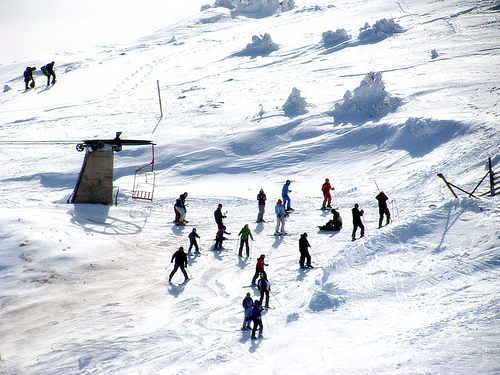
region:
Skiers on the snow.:
[173, 178, 330, 326]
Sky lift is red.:
[92, 121, 169, 204]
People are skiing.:
[246, 174, 375, 275]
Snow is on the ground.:
[31, 236, 157, 373]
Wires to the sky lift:
[16, 134, 74, 158]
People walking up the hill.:
[8, 52, 85, 108]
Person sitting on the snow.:
[315, 209, 341, 235]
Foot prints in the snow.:
[121, 48, 178, 88]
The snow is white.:
[337, 270, 444, 360]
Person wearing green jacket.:
[236, 221, 254, 242]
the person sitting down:
[316, 205, 348, 244]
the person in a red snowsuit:
[310, 175, 343, 208]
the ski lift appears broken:
[1, 130, 163, 216]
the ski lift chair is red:
[124, 143, 169, 211]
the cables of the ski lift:
[0, 137, 82, 152]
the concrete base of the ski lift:
[67, 150, 118, 206]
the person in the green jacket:
[234, 220, 257, 265]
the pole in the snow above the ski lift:
[151, 75, 186, 115]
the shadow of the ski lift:
[59, 197, 155, 247]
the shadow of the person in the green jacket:
[232, 254, 251, 273]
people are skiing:
[122, 36, 478, 361]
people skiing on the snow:
[107, 91, 451, 373]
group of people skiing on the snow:
[164, 132, 423, 368]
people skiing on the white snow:
[112, 111, 452, 344]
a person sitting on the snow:
[309, 200, 355, 252]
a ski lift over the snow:
[62, 93, 207, 235]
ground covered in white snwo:
[157, 31, 299, 170]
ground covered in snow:
[178, 66, 298, 175]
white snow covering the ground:
[204, 38, 354, 159]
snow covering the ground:
[233, 36, 361, 162]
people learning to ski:
[125, 172, 413, 348]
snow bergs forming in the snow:
[336, 36, 424, 131]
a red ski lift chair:
[131, 145, 156, 207]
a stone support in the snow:
[77, 143, 125, 206]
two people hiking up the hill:
[16, 57, 68, 100]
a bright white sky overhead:
[25, 7, 120, 42]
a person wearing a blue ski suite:
[274, 176, 294, 201]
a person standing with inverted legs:
[165, 242, 195, 286]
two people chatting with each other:
[229, 292, 271, 337]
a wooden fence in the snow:
[446, 159, 495, 196]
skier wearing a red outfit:
[321, 178, 334, 208]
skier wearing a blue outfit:
[281, 180, 292, 212]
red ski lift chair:
[132, 145, 154, 202]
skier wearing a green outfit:
[238, 224, 253, 256]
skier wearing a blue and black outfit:
[242, 292, 253, 330]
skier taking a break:
[319, 208, 341, 230]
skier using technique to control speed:
[168, 247, 188, 284]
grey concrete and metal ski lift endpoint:
[68, 132, 155, 205]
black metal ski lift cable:
[1, 140, 85, 145]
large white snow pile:
[328, 71, 398, 126]